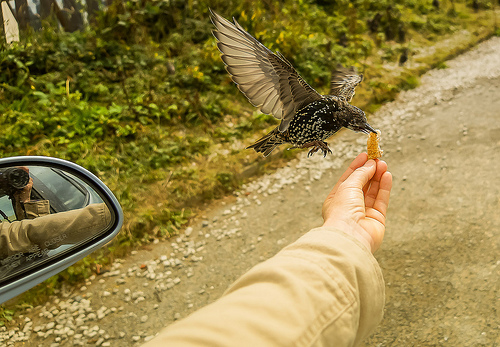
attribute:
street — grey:
[2, 34, 497, 344]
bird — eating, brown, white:
[206, 10, 377, 154]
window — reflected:
[17, 133, 143, 284]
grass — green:
[19, 10, 199, 166]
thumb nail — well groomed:
[360, 156, 377, 178]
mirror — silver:
[0, 137, 157, 308]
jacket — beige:
[133, 219, 386, 344]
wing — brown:
[206, 27, 290, 135]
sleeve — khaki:
[131, 225, 388, 345]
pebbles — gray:
[134, 198, 219, 273]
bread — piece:
[362, 124, 382, 157]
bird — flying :
[183, 7, 399, 172]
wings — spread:
[204, 5, 317, 125]